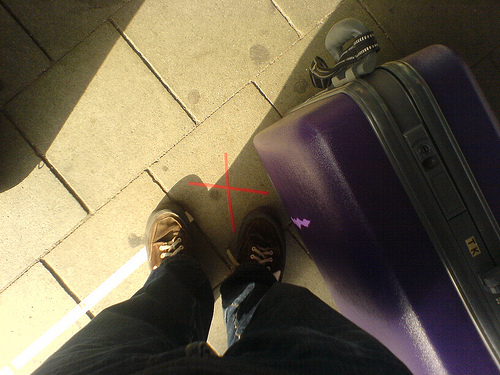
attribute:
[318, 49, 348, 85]
strap — black, white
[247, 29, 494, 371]
suitcase — Large 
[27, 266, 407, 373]
pants — blue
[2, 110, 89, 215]
grout — missing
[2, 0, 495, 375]
walkway — Cement 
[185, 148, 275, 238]
x — Red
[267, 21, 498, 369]
suitcase — plastic, purple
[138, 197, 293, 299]
shoes — brown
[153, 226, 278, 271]
laces — white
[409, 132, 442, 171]
lock — key lock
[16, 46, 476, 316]
ground — Concrete 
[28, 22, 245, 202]
floor — light brown, cement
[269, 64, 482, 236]
suitcase — t k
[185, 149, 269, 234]
x — Red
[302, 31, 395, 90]
strap — Black 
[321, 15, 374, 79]
handle — gray